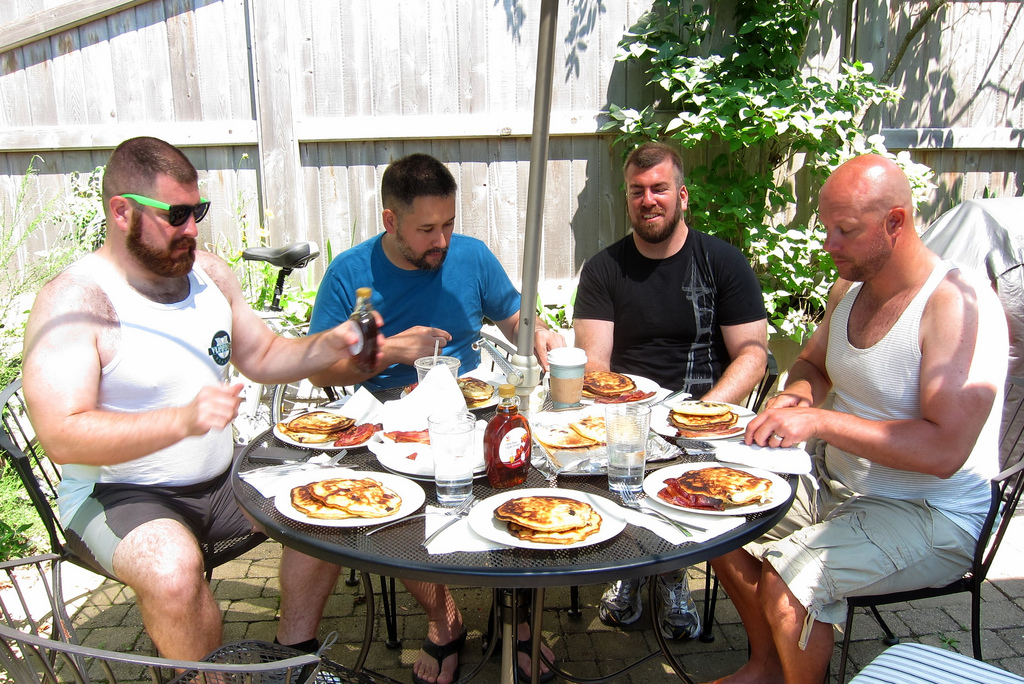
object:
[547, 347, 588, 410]
cup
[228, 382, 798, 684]
table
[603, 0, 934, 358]
tree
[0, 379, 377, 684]
chair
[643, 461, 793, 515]
plate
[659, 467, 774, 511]
food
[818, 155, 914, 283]
head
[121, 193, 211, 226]
sunglasses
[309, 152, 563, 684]
man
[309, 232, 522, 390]
shirt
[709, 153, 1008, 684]
man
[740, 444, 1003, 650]
shorts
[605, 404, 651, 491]
drink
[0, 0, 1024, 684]
patio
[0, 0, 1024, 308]
fence